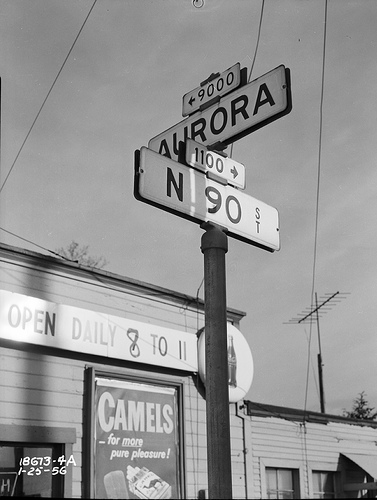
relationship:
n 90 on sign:
[131, 146, 285, 257] [134, 137, 280, 252]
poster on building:
[63, 360, 207, 494] [0, 244, 376, 498]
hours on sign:
[120, 322, 190, 369] [2, 289, 255, 403]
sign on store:
[2, 289, 255, 403] [5, 251, 362, 496]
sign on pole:
[134, 137, 280, 252] [173, 227, 220, 297]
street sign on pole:
[180, 61, 246, 118] [173, 227, 220, 297]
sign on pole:
[137, 62, 313, 175] [173, 227, 220, 297]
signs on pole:
[182, 138, 248, 189] [173, 227, 220, 297]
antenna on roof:
[287, 286, 348, 416] [245, 399, 375, 428]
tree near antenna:
[344, 392, 372, 425] [287, 286, 348, 416]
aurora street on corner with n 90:
[145, 64, 293, 177] [136, 147, 279, 253]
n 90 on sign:
[136, 147, 279, 253] [135, 147, 284, 252]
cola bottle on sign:
[226, 333, 239, 389] [193, 318, 254, 407]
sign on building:
[193, 318, 254, 407] [0, 244, 376, 498]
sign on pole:
[100, 141, 320, 264] [201, 69, 233, 498]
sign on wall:
[137, 62, 313, 175] [0, 246, 245, 496]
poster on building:
[77, 360, 188, 500] [0, 244, 376, 498]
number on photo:
[15, 416, 75, 486] [0, 2, 374, 497]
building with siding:
[0, 244, 376, 498] [0, 401, 83, 423]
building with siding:
[0, 244, 376, 498] [0, 355, 85, 380]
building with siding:
[0, 244, 376, 498] [0, 384, 83, 408]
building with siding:
[0, 244, 376, 498] [0, 267, 205, 330]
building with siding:
[0, 244, 376, 498] [183, 458, 207, 472]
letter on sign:
[160, 166, 183, 201] [134, 137, 280, 252]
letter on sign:
[200, 184, 222, 213] [134, 137, 280, 252]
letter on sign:
[222, 193, 241, 223] [134, 137, 280, 252]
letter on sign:
[254, 207, 261, 217] [134, 137, 280, 252]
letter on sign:
[253, 221, 261, 231] [148, 61, 290, 161]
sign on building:
[2, 289, 254, 370] [0, 244, 376, 498]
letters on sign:
[7, 302, 187, 361] [2, 289, 255, 403]